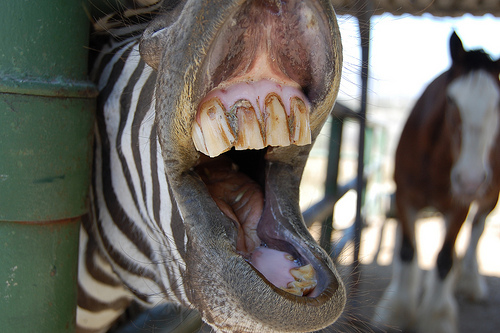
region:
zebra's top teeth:
[177, 91, 317, 152]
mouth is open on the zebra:
[153, 6, 363, 325]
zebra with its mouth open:
[77, 2, 355, 327]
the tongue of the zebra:
[211, 171, 291, 285]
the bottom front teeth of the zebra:
[289, 261, 322, 308]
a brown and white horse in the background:
[369, 29, 496, 328]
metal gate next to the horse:
[289, 93, 406, 271]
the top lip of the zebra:
[159, 1, 341, 120]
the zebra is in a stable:
[2, 8, 387, 332]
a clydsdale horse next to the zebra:
[369, 36, 499, 323]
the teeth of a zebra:
[212, 108, 308, 134]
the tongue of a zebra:
[223, 185, 254, 213]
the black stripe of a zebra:
[135, 110, 140, 139]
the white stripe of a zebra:
[113, 175, 127, 190]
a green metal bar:
[11, 108, 55, 214]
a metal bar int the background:
[357, 133, 368, 187]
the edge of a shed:
[391, 6, 446, 18]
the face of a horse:
[449, 63, 499, 213]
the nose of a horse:
[456, 166, 488, 192]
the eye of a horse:
[446, 91, 456, 106]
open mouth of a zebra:
[84, 0, 349, 330]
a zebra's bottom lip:
[191, 192, 347, 332]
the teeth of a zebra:
[188, 100, 314, 156]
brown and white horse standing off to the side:
[385, 36, 498, 328]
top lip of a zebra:
[162, 0, 343, 105]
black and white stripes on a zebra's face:
[96, 46, 179, 301]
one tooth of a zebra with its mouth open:
[198, 97, 230, 159]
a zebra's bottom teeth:
[288, 259, 317, 296]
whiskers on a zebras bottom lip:
[327, 233, 387, 328]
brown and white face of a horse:
[444, 71, 493, 198]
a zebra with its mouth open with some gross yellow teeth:
[54, 3, 394, 332]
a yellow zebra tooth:
[198, 103, 225, 156]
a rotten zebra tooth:
[227, 95, 248, 134]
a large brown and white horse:
[373, 24, 498, 322]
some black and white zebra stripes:
[100, 151, 157, 275]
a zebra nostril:
[133, 7, 184, 64]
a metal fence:
[309, 111, 372, 295]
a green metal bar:
[0, 18, 87, 324]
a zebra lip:
[259, 293, 348, 327]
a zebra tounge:
[198, 180, 271, 250]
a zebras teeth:
[189, 65, 324, 156]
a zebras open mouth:
[156, 22, 378, 319]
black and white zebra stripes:
[101, 37, 171, 242]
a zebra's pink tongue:
[198, 159, 293, 253]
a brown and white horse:
[391, 25, 491, 304]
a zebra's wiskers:
[331, 2, 373, 127]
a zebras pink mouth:
[237, 228, 319, 302]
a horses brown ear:
[432, 24, 485, 70]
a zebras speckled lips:
[195, 258, 268, 328]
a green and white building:
[16, 42, 71, 251]